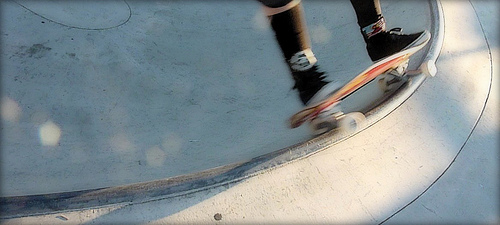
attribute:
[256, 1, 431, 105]
legs — closeup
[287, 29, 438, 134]
skateboard — red, white, colorful, yellow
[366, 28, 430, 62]
sneaker — white, black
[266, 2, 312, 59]
sock — brown, black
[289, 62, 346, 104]
shoe — black, white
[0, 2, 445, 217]
ramp — empty, concrete, grey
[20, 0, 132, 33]
pattern — circular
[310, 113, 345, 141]
wheel — spinning, white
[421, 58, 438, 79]
wheel — white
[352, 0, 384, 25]
sock — brown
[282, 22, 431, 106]
sneakers — black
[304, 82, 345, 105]
sole — white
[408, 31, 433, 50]
sole — white